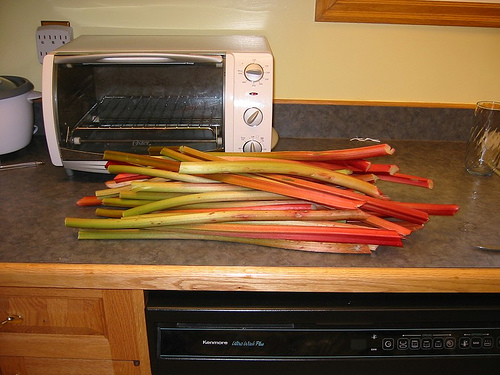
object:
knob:
[242, 62, 265, 84]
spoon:
[472, 240, 500, 258]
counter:
[3, 140, 499, 269]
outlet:
[33, 26, 75, 56]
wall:
[0, 3, 499, 110]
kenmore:
[202, 337, 231, 348]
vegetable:
[53, 141, 452, 255]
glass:
[461, 98, 499, 178]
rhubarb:
[64, 142, 462, 258]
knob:
[234, 101, 269, 129]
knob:
[230, 133, 269, 155]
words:
[195, 339, 270, 351]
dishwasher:
[153, 302, 499, 375]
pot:
[1, 74, 41, 161]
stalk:
[65, 138, 459, 254]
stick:
[63, 138, 462, 258]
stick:
[58, 144, 460, 258]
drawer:
[1, 288, 138, 375]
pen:
[0, 155, 50, 174]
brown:
[58, 306, 88, 329]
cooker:
[40, 29, 273, 179]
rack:
[80, 85, 216, 135]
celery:
[59, 143, 464, 255]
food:
[66, 130, 463, 258]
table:
[0, 106, 494, 267]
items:
[63, 141, 459, 256]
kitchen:
[0, 0, 499, 375]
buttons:
[380, 335, 396, 354]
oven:
[39, 31, 282, 176]